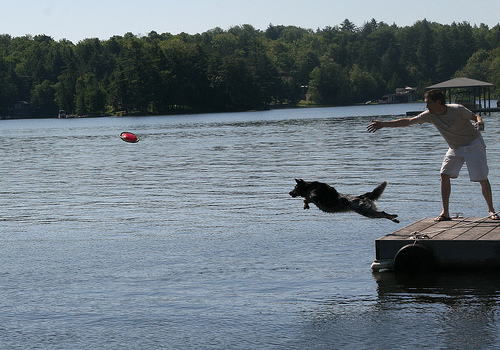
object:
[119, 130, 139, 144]
frisbee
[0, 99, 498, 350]
lake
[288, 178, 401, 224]
dog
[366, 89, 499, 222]
man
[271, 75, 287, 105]
tree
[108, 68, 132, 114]
tree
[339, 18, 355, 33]
tree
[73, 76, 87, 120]
tree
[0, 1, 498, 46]
sky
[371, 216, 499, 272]
dock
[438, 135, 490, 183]
shorts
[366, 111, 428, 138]
arm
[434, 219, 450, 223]
sandal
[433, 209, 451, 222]
foot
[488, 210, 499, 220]
foot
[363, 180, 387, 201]
tail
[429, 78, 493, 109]
gondela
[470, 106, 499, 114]
pier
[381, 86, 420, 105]
house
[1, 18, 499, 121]
woods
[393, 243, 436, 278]
tire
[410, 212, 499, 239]
rope